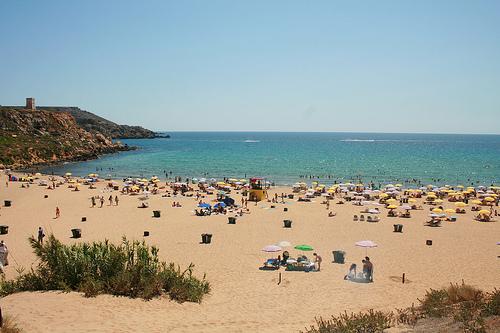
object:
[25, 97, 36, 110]
building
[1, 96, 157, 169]
hill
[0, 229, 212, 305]
shrub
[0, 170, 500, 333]
beach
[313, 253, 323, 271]
person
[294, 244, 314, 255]
umbrella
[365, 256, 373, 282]
person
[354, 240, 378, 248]
umbrella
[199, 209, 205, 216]
person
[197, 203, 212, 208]
umbrella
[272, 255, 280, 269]
person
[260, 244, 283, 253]
umbrella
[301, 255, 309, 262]
person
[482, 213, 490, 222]
person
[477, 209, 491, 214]
umbrella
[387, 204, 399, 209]
umbrella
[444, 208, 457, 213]
umbrella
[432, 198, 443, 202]
umbrella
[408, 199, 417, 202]
umbrella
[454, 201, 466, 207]
umbrella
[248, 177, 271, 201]
lifeguard stand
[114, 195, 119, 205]
person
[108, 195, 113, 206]
person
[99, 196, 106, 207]
person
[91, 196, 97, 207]
person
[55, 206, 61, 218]
person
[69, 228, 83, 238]
trash can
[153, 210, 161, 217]
trash can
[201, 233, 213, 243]
trash can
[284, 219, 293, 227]
trash can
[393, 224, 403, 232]
trash can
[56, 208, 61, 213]
shirt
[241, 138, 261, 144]
wave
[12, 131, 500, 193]
ocean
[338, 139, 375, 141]
wave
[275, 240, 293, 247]
umbrella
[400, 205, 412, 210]
umbrella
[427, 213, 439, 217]
umbrella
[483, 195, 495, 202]
umbrella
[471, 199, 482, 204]
umbrella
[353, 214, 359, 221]
chair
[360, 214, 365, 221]
chair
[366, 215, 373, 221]
chair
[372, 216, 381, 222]
chair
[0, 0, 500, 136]
sky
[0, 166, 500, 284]
crowd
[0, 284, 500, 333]
dune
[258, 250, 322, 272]
group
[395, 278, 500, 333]
bush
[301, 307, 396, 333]
bush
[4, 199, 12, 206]
trash can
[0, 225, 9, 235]
trash can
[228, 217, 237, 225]
trash can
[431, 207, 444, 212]
umbrellas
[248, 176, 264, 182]
umbrella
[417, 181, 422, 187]
people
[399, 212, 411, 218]
person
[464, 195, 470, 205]
person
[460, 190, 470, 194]
umbrella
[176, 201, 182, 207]
person